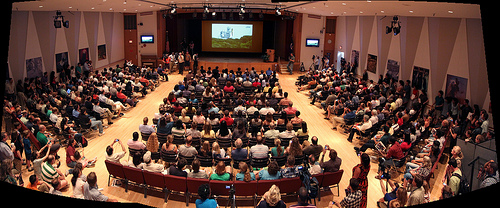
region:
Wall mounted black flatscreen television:
[137, 31, 154, 46]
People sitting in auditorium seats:
[2, 0, 497, 206]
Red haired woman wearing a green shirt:
[208, 155, 232, 183]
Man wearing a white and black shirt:
[338, 175, 365, 206]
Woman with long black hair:
[215, 116, 232, 142]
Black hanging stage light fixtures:
[161, 3, 296, 27]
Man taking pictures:
[318, 142, 342, 193]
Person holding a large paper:
[373, 133, 404, 179]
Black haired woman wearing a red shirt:
[398, 125, 412, 150]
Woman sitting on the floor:
[62, 135, 97, 168]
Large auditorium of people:
[1, 3, 498, 207]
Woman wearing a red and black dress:
[350, 151, 371, 206]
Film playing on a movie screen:
[197, 17, 264, 55]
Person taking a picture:
[104, 135, 126, 166]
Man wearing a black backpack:
[447, 155, 470, 199]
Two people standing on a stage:
[175, 37, 196, 56]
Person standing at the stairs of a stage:
[285, 48, 297, 74]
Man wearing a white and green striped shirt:
[40, 151, 59, 186]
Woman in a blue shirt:
[193, 179, 219, 206]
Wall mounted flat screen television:
[303, 35, 320, 49]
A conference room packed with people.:
[0, 3, 499, 207]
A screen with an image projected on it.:
[200, 17, 265, 54]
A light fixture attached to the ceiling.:
[382, 13, 403, 35]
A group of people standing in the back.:
[192, 144, 498, 206]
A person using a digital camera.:
[102, 137, 127, 167]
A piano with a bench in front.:
[138, 52, 158, 69]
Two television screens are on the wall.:
[139, 33, 319, 48]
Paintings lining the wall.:
[350, 49, 467, 101]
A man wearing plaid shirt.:
[339, 178, 364, 207]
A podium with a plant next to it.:
[260, 45, 276, 62]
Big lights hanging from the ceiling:
[378, 15, 408, 41]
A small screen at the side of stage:
[305, 34, 323, 50]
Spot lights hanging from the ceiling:
[161, 5, 293, 22]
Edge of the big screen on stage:
[246, 19, 258, 27]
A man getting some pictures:
[103, 135, 130, 162]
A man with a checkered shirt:
[339, 179, 363, 206]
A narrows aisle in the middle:
[283, 73, 340, 142]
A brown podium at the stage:
[261, 44, 278, 66]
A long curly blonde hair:
[144, 130, 161, 150]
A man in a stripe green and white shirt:
[39, 152, 66, 179]